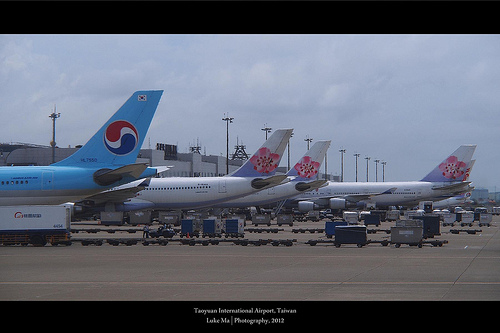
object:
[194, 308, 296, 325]
text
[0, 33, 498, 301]
photo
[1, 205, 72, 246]
service vehicle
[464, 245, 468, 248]
white lines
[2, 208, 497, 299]
ground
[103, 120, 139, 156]
logo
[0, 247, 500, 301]
concrete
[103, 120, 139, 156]
swirl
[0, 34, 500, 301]
airport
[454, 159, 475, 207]
tails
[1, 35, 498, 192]
skies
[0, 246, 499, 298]
pavement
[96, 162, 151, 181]
wings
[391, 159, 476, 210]
plane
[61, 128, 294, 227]
aircraft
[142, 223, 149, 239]
mechanic crew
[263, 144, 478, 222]
aircraft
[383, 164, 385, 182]
light pole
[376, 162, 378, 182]
light pole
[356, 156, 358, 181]
light pole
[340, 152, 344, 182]
light pole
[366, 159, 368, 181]
light pole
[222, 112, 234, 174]
light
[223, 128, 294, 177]
tail fins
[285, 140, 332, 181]
tail fins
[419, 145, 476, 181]
tail fins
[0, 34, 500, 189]
clouds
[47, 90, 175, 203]
tail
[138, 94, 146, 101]
flag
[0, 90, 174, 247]
aircraft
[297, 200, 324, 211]
engine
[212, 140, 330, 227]
aircraft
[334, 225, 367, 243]
luggage boxes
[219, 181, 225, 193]
door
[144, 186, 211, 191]
windows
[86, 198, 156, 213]
engine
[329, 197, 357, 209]
engines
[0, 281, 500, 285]
line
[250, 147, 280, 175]
flower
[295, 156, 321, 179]
flower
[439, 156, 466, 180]
flower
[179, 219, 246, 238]
carts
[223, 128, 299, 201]
tail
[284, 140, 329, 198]
tail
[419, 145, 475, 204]
tail